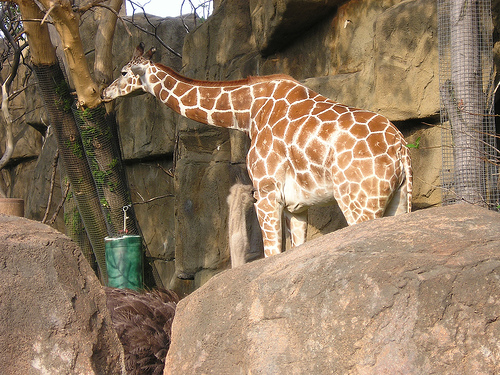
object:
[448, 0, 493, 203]
fencing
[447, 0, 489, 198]
tree trunk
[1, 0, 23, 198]
branch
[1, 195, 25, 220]
planter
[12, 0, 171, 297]
tree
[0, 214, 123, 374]
rock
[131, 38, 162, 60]
horns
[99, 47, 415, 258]
girafee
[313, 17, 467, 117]
rock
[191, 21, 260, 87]
rock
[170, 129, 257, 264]
rock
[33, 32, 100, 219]
rock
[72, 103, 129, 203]
moss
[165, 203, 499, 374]
boulder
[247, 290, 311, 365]
highlights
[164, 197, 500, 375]
surface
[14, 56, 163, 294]
mesh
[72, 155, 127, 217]
leaves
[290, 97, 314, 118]
spots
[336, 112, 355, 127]
spots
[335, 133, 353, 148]
spots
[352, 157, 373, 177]
spots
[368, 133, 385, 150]
spots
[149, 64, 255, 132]
neck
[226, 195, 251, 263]
ostrich neck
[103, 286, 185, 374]
feathers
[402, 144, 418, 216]
giraffe tail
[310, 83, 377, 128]
ground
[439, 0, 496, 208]
tree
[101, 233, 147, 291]
bucket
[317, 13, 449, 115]
wall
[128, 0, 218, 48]
branches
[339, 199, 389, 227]
feet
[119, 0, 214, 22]
sky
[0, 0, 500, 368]
pen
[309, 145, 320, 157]
white spots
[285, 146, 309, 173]
brown patch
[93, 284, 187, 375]
ostrich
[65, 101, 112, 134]
leaves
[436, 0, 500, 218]
mesh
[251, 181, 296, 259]
front feet